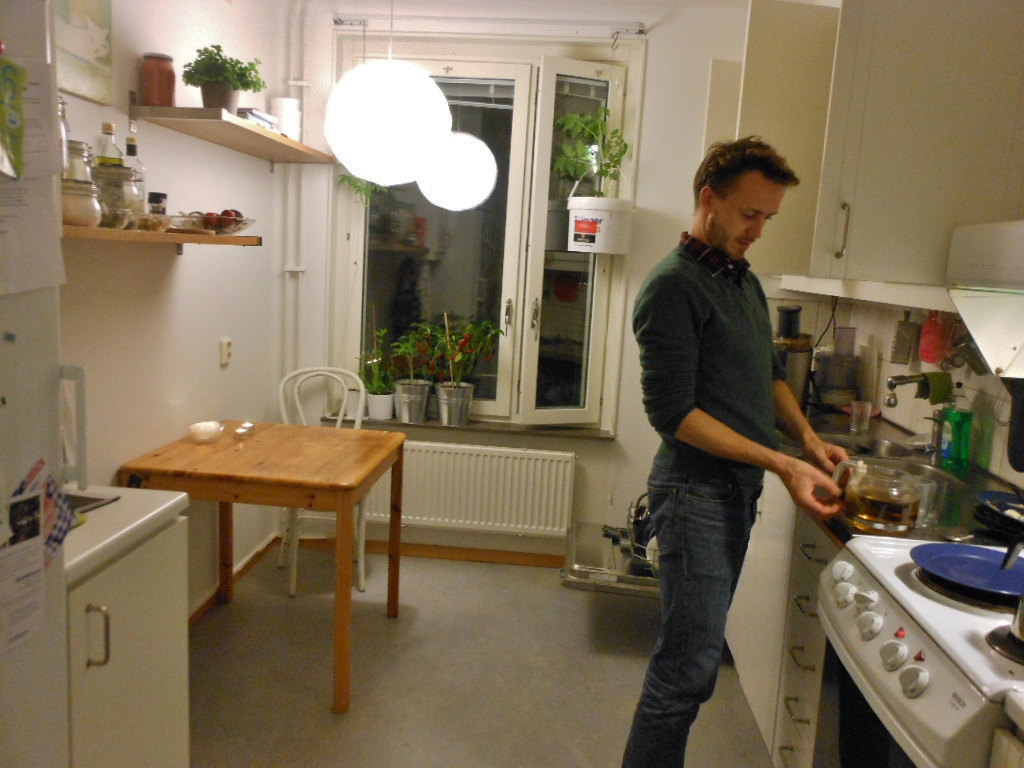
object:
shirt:
[629, 234, 780, 468]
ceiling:
[46, 4, 752, 30]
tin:
[436, 379, 475, 431]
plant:
[551, 102, 631, 200]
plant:
[335, 174, 389, 204]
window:
[532, 60, 622, 414]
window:
[350, 44, 531, 427]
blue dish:
[912, 527, 1022, 609]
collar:
[677, 230, 756, 276]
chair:
[277, 366, 376, 598]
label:
[573, 217, 600, 243]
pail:
[566, 164, 631, 254]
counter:
[778, 392, 1024, 536]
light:
[325, 56, 453, 187]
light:
[419, 130, 499, 210]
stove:
[811, 523, 1021, 765]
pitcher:
[842, 458, 928, 534]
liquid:
[849, 486, 921, 529]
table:
[115, 418, 406, 716]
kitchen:
[5, 1, 1024, 761]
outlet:
[219, 337, 233, 366]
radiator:
[302, 430, 578, 541]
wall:
[47, 0, 832, 626]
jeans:
[625, 440, 768, 761]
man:
[624, 123, 849, 762]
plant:
[432, 310, 493, 386]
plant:
[395, 313, 434, 383]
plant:
[359, 322, 402, 394]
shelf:
[132, 95, 333, 165]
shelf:
[63, 219, 262, 248]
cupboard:
[74, 513, 195, 766]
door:
[778, 683, 824, 735]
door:
[788, 559, 824, 645]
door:
[775, 715, 832, 766]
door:
[780, 629, 832, 687]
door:
[794, 512, 837, 573]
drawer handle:
[770, 740, 802, 766]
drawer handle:
[777, 681, 816, 727]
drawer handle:
[778, 633, 825, 681]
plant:
[181, 44, 268, 94]